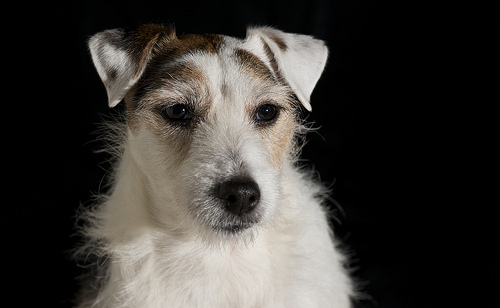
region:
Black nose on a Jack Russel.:
[225, 161, 266, 222]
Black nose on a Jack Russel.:
[263, 164, 308, 205]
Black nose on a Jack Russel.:
[185, 27, 233, 98]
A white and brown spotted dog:
[61, 15, 358, 302]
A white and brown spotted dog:
[70, 15, 360, 305]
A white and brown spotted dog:
[75, 17, 365, 304]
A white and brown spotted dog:
[70, 17, 365, 304]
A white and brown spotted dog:
[66, 18, 366, 304]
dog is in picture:
[60, 40, 346, 298]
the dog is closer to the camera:
[129, 62, 311, 259]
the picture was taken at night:
[137, 30, 410, 272]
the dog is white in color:
[128, 44, 326, 304]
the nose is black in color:
[211, 164, 297, 244]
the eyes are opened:
[151, 69, 303, 159]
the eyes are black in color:
[193, 105, 310, 152]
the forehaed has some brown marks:
[162, 22, 283, 149]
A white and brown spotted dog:
[70, 22, 358, 306]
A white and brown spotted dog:
[65, 22, 359, 306]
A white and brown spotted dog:
[67, 18, 352, 306]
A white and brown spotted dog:
[75, 21, 367, 305]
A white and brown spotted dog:
[77, 21, 359, 305]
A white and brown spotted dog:
[71, 19, 352, 306]